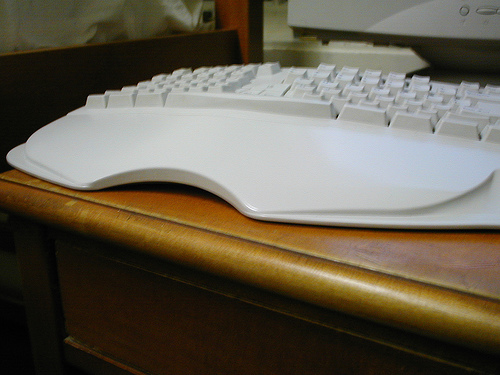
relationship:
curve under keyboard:
[103, 169, 235, 222] [8, 63, 499, 237]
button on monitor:
[458, 4, 468, 16] [285, 2, 499, 63]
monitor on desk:
[286, 0, 498, 72] [4, 167, 499, 373]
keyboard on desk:
[8, 63, 499, 237] [13, 116, 484, 342]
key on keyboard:
[89, 63, 500, 136] [8, 63, 499, 237]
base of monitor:
[402, 44, 499, 86] [286, 2, 498, 41]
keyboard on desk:
[8, 63, 499, 237] [7, 131, 495, 362]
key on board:
[89, 63, 500, 136] [12, 56, 497, 232]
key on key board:
[169, 89, 335, 126] [37, 44, 498, 236]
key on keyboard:
[89, 63, 500, 136] [95, 45, 490, 244]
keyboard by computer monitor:
[8, 0, 499, 237] [284, 0, 498, 84]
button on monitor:
[455, 4, 472, 20] [281, 0, 498, 82]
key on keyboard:
[89, 63, 500, 136] [115, 49, 499, 154]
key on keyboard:
[89, 63, 500, 136] [181, 18, 498, 180]